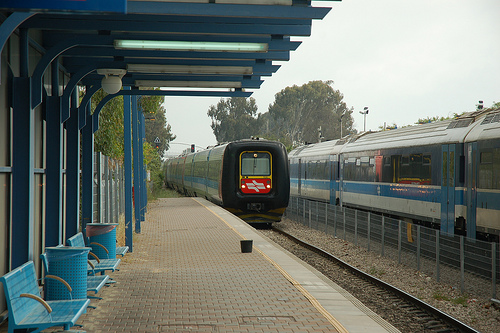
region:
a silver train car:
[206, 136, 288, 226]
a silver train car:
[182, 149, 194, 194]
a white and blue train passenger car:
[336, 108, 483, 245]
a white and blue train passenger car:
[460, 104, 497, 264]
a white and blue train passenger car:
[285, 128, 348, 212]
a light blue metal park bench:
[4, 256, 89, 328]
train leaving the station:
[173, 138, 300, 223]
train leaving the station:
[179, 128, 348, 248]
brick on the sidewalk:
[159, 248, 224, 301]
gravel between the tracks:
[328, 229, 374, 276]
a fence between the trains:
[367, 210, 412, 268]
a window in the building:
[32, 147, 60, 227]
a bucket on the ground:
[235, 226, 263, 262]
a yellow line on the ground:
[304, 282, 329, 326]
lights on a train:
[235, 173, 253, 198]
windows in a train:
[348, 147, 399, 188]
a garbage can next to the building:
[55, 235, 107, 323]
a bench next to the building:
[74, 228, 139, 294]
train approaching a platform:
[155, 132, 297, 234]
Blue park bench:
[6, 251, 91, 327]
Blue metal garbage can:
[79, 216, 124, 268]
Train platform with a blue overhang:
[1, 4, 346, 331]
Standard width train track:
[197, 190, 475, 331]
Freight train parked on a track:
[283, 109, 497, 264]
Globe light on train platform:
[86, 62, 133, 103]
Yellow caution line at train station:
[186, 195, 356, 332]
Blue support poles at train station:
[115, 84, 156, 251]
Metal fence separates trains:
[285, 190, 499, 295]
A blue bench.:
[4, 248, 82, 331]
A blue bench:
[65, 226, 133, 281]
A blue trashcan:
[44, 240, 104, 308]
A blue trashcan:
[85, 212, 131, 267]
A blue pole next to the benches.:
[115, 90, 145, 252]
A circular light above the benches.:
[98, 71, 121, 92]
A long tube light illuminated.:
[115, 35, 280, 61]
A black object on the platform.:
[235, 230, 262, 255]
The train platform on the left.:
[142, 182, 263, 327]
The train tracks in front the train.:
[271, 219, 341, 261]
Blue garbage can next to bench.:
[0, 223, 125, 319]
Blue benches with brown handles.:
[2, 216, 135, 330]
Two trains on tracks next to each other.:
[151, 98, 494, 279]